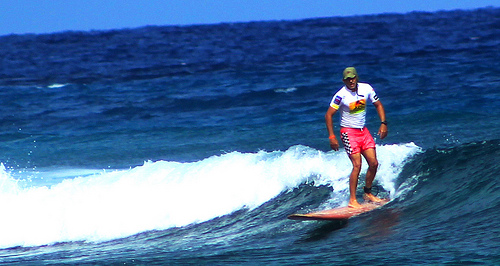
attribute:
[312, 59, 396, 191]
man — surfing, tan, dark, riding, buff, close, wet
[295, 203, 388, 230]
surboard — white, red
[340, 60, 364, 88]
cap — green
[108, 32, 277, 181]
water — rapid, white, blue, foamy, dark, crashing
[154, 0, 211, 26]
sky — clear, spotless, blue, bright